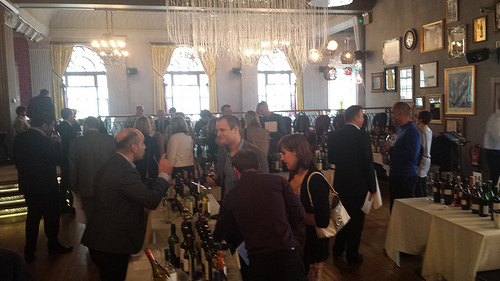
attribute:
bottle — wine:
[426, 161, 493, 216]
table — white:
[389, 191, 487, 275]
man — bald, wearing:
[59, 115, 153, 215]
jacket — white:
[163, 129, 196, 174]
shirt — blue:
[387, 120, 418, 174]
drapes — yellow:
[306, 154, 348, 273]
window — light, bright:
[155, 27, 213, 110]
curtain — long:
[40, 39, 83, 133]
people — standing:
[60, 69, 394, 232]